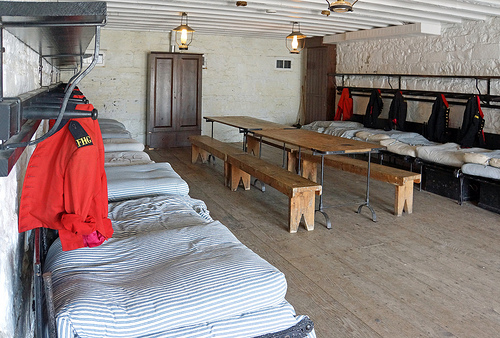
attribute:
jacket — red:
[32, 111, 117, 238]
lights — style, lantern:
[167, 10, 307, 55]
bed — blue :
[108, 157, 195, 204]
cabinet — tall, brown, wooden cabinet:
[144, 53, 202, 151]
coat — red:
[325, 80, 361, 132]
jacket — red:
[15, 102, 112, 251]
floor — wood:
[232, 199, 499, 329]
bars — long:
[329, 70, 499, 79]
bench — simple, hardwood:
[224, 150, 324, 235]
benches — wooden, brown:
[188, 129, 420, 232]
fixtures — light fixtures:
[169, 10, 311, 61]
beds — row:
[111, 130, 260, 329]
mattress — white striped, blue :
[47, 198, 267, 335]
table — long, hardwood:
[183, 111, 383, 233]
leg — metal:
[308, 147, 335, 234]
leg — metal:
[353, 145, 380, 224]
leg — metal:
[241, 127, 271, 193]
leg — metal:
[205, 115, 218, 162]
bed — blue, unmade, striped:
[44, 207, 301, 335]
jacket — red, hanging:
[335, 88, 354, 116]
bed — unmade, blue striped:
[453, 136, 496, 168]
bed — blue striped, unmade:
[384, 127, 431, 157]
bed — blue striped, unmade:
[422, 133, 474, 165]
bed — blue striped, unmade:
[305, 116, 357, 140]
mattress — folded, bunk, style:
[46, 116, 316, 328]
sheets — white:
[57, 200, 286, 333]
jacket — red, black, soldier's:
[423, 92, 453, 183]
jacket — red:
[16, 118, 113, 252]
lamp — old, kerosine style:
[286, 30, 304, 53]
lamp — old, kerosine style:
[171, 24, 195, 46]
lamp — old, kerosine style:
[326, 0, 358, 14]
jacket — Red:
[18, 102, 119, 252]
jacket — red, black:
[356, 85, 386, 137]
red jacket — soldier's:
[332, 87, 358, 123]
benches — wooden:
[181, 115, 430, 237]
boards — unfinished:
[148, 142, 498, 336]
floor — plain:
[147, 136, 497, 335]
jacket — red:
[6, 97, 114, 260]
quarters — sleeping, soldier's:
[30, 35, 472, 326]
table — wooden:
[273, 111, 381, 238]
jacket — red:
[40, 99, 109, 263]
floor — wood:
[333, 238, 452, 328]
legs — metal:
[309, 159, 376, 226]